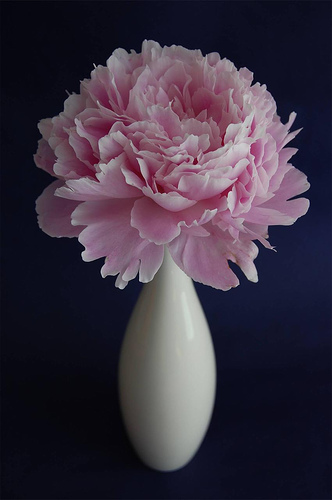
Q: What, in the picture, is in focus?
A: The flower.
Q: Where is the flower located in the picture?
A: In the center.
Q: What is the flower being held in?
A: A vase.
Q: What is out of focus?
A: The vase.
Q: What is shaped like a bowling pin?
A: A vase.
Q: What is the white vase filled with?
A: Flowers.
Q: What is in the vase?
A: A pink flower.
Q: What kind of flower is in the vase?
A: A pink peony with white tips.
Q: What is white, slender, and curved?
A: A vase.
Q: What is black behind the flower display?
A: The background.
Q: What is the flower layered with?
A: Petals.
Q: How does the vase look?
A: Distant.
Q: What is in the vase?
A: A flower.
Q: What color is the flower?
A: Pink.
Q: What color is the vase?
A: White.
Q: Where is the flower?
A: In the vase.